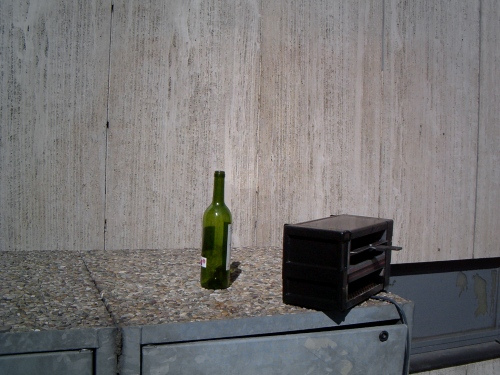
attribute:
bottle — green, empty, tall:
[193, 165, 238, 293]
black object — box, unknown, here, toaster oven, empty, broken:
[270, 206, 404, 321]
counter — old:
[4, 238, 421, 374]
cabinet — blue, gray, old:
[5, 294, 421, 374]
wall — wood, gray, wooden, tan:
[3, 1, 500, 256]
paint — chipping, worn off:
[453, 270, 492, 318]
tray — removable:
[348, 238, 395, 264]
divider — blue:
[380, 256, 493, 374]